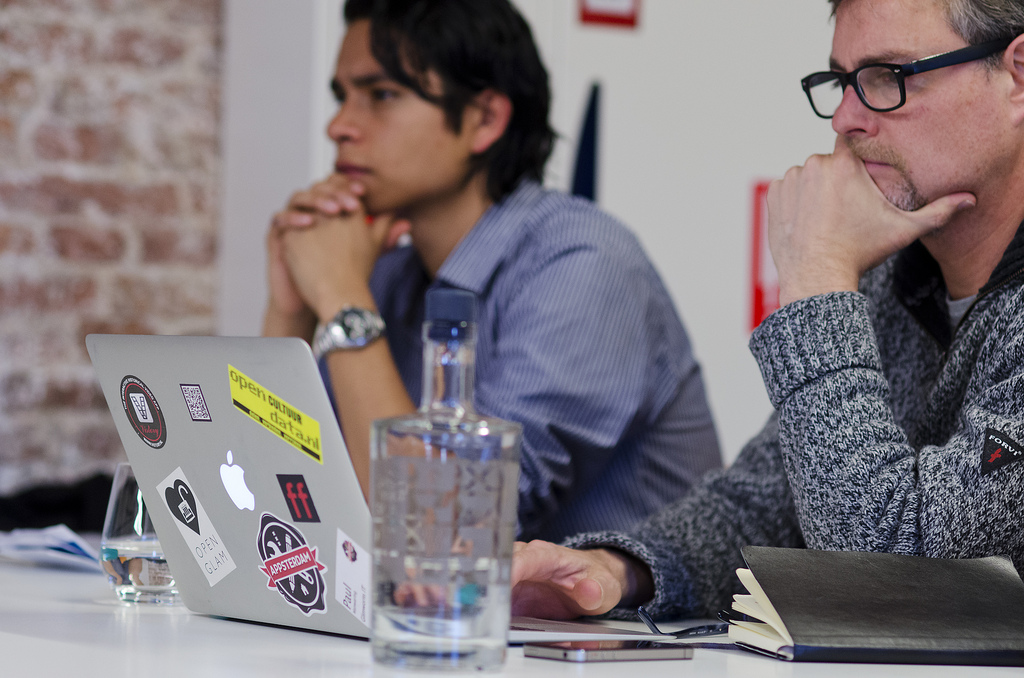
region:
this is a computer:
[128, 318, 443, 601]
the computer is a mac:
[114, 358, 468, 653]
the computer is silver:
[242, 432, 467, 666]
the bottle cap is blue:
[386, 262, 561, 373]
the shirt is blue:
[438, 139, 651, 463]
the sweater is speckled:
[699, 288, 1020, 589]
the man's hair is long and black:
[371, 40, 648, 259]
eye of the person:
[877, 70, 912, 97]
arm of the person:
[816, 401, 930, 513]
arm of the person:
[261, 307, 332, 355]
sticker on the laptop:
[266, 500, 343, 605]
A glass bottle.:
[368, 275, 555, 675]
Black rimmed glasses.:
[791, 23, 1008, 125]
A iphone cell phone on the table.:
[526, 617, 694, 666]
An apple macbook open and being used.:
[64, 317, 660, 660]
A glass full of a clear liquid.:
[58, 421, 232, 618]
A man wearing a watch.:
[232, 7, 746, 574]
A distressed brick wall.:
[4, 7, 229, 545]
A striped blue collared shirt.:
[302, 178, 723, 581]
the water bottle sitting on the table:
[366, 278, 525, 675]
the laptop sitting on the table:
[79, 328, 667, 646]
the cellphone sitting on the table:
[530, 633, 693, 669]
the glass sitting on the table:
[103, 467, 170, 595]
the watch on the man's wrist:
[313, 301, 383, 368]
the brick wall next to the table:
[6, 4, 218, 480]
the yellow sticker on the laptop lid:
[218, 361, 327, 466]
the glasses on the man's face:
[797, 34, 991, 118]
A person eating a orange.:
[675, 488, 792, 625]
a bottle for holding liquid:
[366, 283, 516, 675]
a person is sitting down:
[511, 11, 1021, 619]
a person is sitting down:
[269, 8, 721, 521]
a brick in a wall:
[51, 222, 129, 257]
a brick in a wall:
[133, 219, 217, 265]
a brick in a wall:
[110, 263, 221, 314]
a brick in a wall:
[0, 269, 106, 318]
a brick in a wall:
[3, 361, 108, 415]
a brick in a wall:
[0, 409, 63, 483]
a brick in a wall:
[38, 17, 182, 74]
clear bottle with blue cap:
[367, 281, 513, 675]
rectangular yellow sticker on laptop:
[235, 367, 325, 457]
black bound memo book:
[727, 550, 1022, 668]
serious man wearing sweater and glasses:
[513, 0, 1022, 675]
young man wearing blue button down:
[260, 0, 729, 512]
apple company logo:
[219, 449, 259, 523]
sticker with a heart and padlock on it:
[159, 463, 224, 594]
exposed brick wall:
[0, 6, 237, 498]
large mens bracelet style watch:
[300, 310, 405, 364]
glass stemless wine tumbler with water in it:
[98, 456, 185, 612]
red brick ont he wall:
[11, 151, 98, 224]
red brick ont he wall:
[146, 154, 198, 227]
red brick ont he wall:
[61, 247, 93, 299]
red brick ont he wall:
[122, 98, 195, 217]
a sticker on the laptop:
[207, 347, 338, 490]